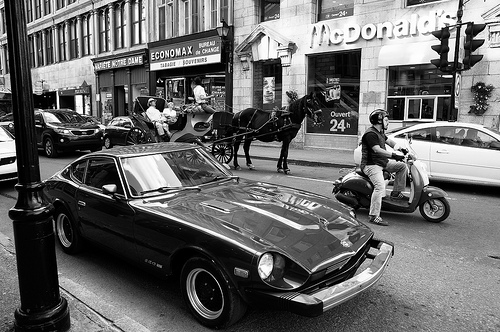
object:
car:
[39, 140, 393, 328]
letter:
[330, 27, 343, 44]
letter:
[309, 25, 333, 49]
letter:
[343, 22, 360, 42]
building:
[231, 0, 498, 162]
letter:
[376, 21, 395, 41]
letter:
[392, 12, 420, 39]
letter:
[354, 18, 375, 42]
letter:
[180, 43, 195, 61]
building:
[0, 0, 236, 163]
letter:
[170, 41, 194, 69]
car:
[355, 114, 497, 195]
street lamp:
[196, 1, 236, 168]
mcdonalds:
[232, 0, 497, 154]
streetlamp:
[0, 1, 74, 330]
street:
[0, 110, 493, 329]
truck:
[5, 103, 105, 156]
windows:
[382, 66, 456, 124]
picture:
[0, 1, 498, 330]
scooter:
[329, 146, 455, 228]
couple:
[122, 95, 182, 142]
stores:
[149, 28, 231, 130]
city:
[0, 0, 500, 332]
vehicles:
[0, 84, 500, 332]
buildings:
[232, 3, 500, 147]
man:
[354, 105, 412, 226]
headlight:
[252, 250, 278, 284]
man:
[143, 96, 177, 146]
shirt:
[140, 106, 178, 127]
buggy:
[117, 93, 220, 142]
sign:
[366, 22, 456, 86]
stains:
[381, 295, 441, 310]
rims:
[174, 258, 257, 328]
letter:
[159, 55, 207, 65]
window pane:
[126, 1, 142, 45]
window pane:
[137, 0, 147, 41]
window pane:
[380, 97, 407, 118]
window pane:
[406, 96, 423, 121]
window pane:
[434, 96, 453, 124]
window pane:
[381, 66, 455, 96]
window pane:
[305, 50, 359, 136]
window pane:
[250, 58, 283, 113]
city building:
[227, 0, 475, 136]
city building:
[0, 1, 225, 136]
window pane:
[69, 12, 89, 32]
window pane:
[68, 14, 94, 40]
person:
[186, 75, 218, 110]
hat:
[147, 90, 168, 108]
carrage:
[123, 59, 242, 164]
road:
[0, 110, 500, 327]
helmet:
[369, 112, 390, 134]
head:
[362, 105, 397, 131]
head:
[301, 79, 336, 133]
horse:
[205, 82, 334, 173]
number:
[329, 109, 348, 149]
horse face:
[298, 73, 334, 135]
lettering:
[287, 0, 494, 90]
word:
[136, 40, 197, 62]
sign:
[138, 32, 228, 77]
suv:
[24, 101, 120, 156]